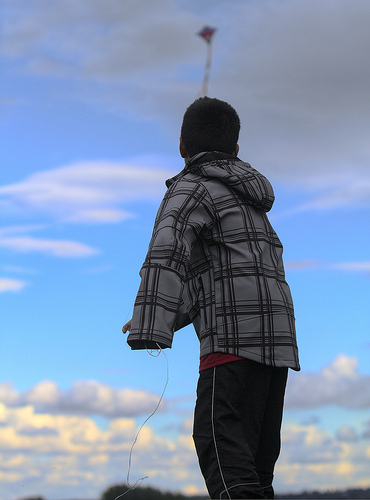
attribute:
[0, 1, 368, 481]
sky — blue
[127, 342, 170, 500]
string — white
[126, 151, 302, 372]
jacket — grey, plaid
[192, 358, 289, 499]
pants — black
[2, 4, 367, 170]
top clouds — grey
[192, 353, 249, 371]
shirt — red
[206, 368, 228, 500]
lines — white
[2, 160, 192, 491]
clouds — white, puffy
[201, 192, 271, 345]
pattern — plaid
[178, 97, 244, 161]
hair — dark, black